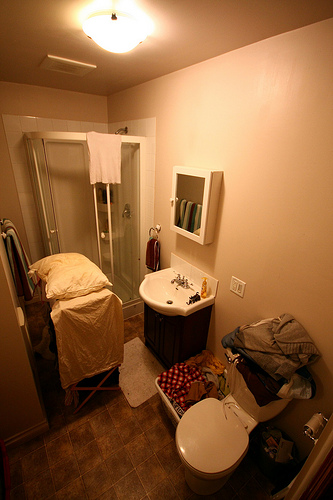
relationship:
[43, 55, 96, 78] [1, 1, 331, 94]
ventilation in ceiling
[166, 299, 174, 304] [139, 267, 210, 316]
drain hole for basin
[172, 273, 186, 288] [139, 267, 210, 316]
taps on basin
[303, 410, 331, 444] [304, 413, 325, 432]
mounting for toilet roll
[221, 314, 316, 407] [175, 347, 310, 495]
pile of clothes on back of toilet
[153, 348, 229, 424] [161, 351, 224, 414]
laundry basket holding clothes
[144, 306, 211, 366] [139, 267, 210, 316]
cabinet under basin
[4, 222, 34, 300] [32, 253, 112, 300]
towel hanging behind pillow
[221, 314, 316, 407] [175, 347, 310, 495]
pile of clothes stacked on toilet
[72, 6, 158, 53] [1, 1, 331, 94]
light fixture on ceiling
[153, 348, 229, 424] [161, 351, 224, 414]
laundry basket full of clothes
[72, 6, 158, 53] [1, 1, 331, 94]
light fixture in ceiling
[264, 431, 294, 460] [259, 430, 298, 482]
trash in trash can